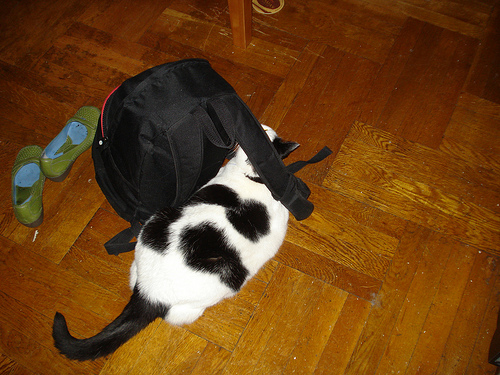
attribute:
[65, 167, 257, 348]
cat — black, whtie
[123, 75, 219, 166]
bag — black, brown, full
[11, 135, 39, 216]
shoe — green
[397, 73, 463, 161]
floor — brown